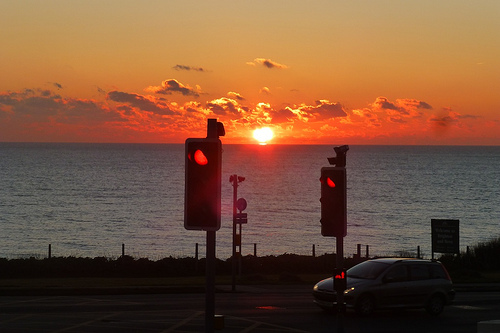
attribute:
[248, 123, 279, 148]
sun — setting, orange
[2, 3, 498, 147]
sky — orange, various colors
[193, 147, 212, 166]
light — red, installed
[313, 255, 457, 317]
car — driving, grey, parked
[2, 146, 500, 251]
ocean — large, body of water, distant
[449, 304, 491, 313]
paint — white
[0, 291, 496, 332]
road — exsisting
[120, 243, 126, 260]
post — along the lot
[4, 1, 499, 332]
scene — in the evening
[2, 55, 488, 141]
clouds — illuminated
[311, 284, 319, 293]
light — red